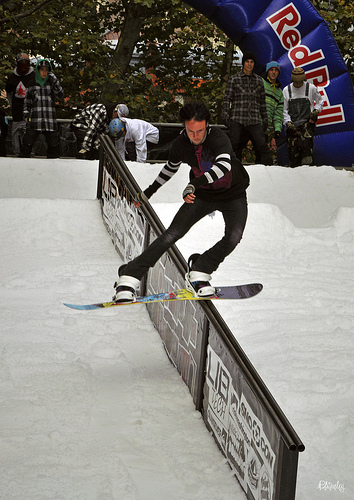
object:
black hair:
[134, 86, 243, 147]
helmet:
[109, 118, 125, 141]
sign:
[63, 302, 107, 312]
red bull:
[265, 2, 347, 127]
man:
[282, 66, 324, 166]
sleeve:
[312, 84, 325, 113]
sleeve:
[282, 85, 292, 126]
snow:
[0, 199, 100, 273]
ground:
[0, 336, 354, 496]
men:
[5, 52, 36, 157]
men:
[69, 102, 160, 163]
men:
[4, 51, 64, 159]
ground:
[2, 158, 348, 337]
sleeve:
[188, 134, 232, 186]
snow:
[35, 327, 175, 483]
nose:
[193, 132, 198, 138]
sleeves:
[273, 92, 284, 133]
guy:
[112, 101, 250, 304]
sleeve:
[141, 150, 183, 202]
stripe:
[214, 153, 231, 163]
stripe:
[216, 160, 232, 171]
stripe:
[208, 164, 225, 178]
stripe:
[155, 160, 182, 186]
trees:
[0, 0, 110, 56]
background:
[6, 1, 343, 62]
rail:
[204, 298, 305, 454]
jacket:
[23, 79, 65, 132]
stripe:
[203, 172, 214, 184]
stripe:
[205, 169, 218, 182]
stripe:
[210, 165, 229, 173]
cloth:
[211, 135, 231, 171]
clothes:
[114, 117, 158, 162]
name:
[316, 480, 345, 494]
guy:
[22, 58, 64, 158]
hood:
[35, 59, 52, 88]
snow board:
[62, 282, 263, 311]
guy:
[259, 61, 285, 166]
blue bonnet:
[265, 61, 280, 71]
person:
[68, 102, 129, 159]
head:
[178, 100, 211, 145]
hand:
[182, 183, 196, 204]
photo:
[51, 185, 295, 363]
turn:
[111, 192, 249, 306]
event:
[29, 187, 304, 378]